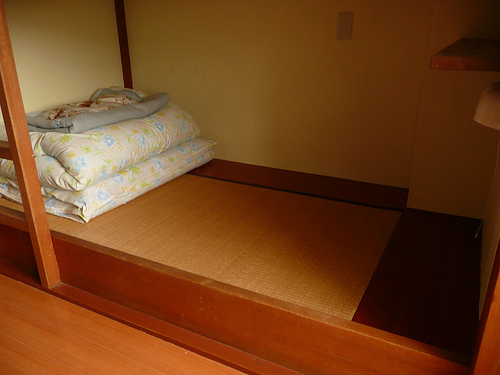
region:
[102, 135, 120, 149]
Blue flower on pillow case.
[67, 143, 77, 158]
Yellow flower on pillow case.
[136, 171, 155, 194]
Green flower on top of pillow case.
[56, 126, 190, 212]
Two pillow on top of floor.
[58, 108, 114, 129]
Blue blanket on top of pillow.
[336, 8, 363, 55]
Socket on side of the wall.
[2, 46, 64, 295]
Brown ladder on the side of bed.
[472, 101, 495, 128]
Small white lamp shade to the right.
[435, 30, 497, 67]
Brown cover over light.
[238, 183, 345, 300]
Thin piece of covering on the floor.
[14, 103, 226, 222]
white with blue flowers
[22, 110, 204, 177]
white yellow and blue comforter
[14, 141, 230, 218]
white yellow and blue sheet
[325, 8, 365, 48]
plate cover on wall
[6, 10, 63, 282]
ladder for top of bunk bed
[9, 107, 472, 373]
bottom bunk of bunk beds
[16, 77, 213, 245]
white yellow and blue flowered sheets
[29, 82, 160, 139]
blue fabric on top of stack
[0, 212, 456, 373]
wooden bed side railing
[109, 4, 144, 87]
corner trim of wall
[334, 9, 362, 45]
ELECTRICAL SOCKET IS ON BACK WALL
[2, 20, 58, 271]
LADDER IS ATTACHED TO THE TOP AND BOTTOM BED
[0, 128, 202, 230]
LINENS ARE AT THE HEAD OF THE BED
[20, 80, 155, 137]
BLANKET IS A BABY BLUE COLOR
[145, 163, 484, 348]
BASE OF BED IS WOODEN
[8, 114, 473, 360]
BED IS BROWN AND TAN IN COLOR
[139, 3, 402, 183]
WALLS ARE OF A YELLOW COLOR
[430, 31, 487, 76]
SHELF IS HUNG ON THE RIGHT WALL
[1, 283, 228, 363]
FLOOR CONSIST OF WOODEN PLANKS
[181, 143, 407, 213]
BED HAS MOLDING AROUND THE BASE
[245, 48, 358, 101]
yellow paint on wall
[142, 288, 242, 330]
wooden frame on side of bed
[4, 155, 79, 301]
tall brown wooden frame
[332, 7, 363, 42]
small outlet on wall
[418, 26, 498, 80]
edge of brown counter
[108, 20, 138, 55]
brown border on wall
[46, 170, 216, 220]
flower motif sheet on bed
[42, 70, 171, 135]
blue sheet on the bed frame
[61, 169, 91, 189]
wrinkle in the sheet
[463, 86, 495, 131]
edge of white fabric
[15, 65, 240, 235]
blankets on the surface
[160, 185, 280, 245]
brown surface under blankets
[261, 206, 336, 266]
shadow on the surface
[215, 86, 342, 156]
wall in the photo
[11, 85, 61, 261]
brown pillar in the photo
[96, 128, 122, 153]
blue design on blanket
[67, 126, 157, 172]
designs on the blanket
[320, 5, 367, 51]
outlet on the wall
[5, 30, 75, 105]
light hitting the wall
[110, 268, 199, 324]
brown piece of wood